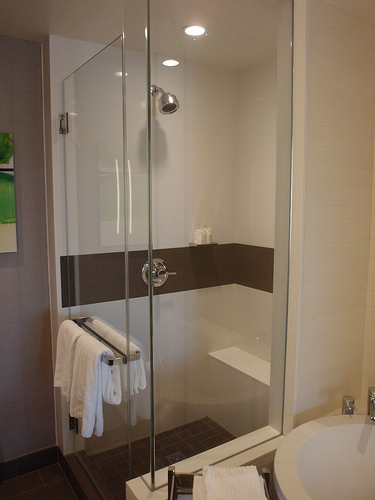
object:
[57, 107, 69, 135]
hinge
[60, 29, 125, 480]
panel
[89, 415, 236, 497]
tile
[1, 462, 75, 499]
floor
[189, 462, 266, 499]
towel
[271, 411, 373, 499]
sink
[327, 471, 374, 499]
basin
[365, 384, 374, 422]
faucet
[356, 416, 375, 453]
shadow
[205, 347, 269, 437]
seat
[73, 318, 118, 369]
handle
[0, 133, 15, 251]
picture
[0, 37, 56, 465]
wall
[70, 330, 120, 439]
towel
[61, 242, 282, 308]
stripe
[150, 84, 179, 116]
fixture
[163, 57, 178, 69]
light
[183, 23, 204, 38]
light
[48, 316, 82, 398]
towel